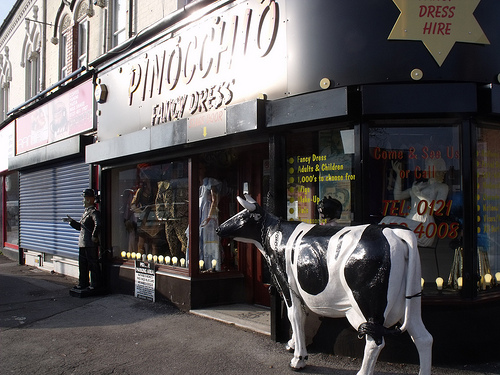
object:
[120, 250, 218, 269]
bulbs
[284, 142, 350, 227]
door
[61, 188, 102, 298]
statue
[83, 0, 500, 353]
store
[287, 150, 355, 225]
lettering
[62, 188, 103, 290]
man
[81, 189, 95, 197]
hat